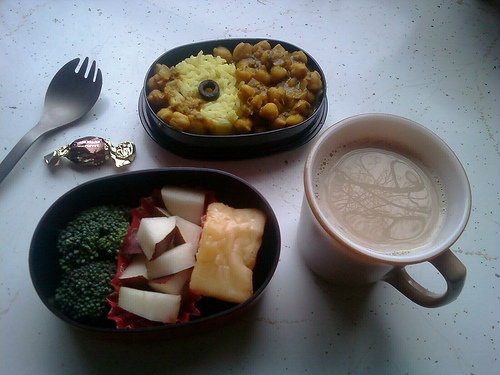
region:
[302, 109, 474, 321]
coffee in coffee mug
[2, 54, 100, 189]
plastic gray fork spoon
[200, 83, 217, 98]
lone black sliced olive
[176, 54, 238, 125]
yellow cooked rice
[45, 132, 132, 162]
candy with yellow and brown candy wrapper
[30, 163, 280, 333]
black plastic round dish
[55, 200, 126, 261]
green cooked broccolli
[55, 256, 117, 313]
green broccolli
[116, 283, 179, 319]
slice of potato with skin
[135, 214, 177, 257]
slice of potato with skin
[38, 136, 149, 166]
a wrapped sweet on the table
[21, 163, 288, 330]
a plate of food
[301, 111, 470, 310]
a white cup of coffee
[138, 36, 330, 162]
a plate of food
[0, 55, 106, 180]
a black fork on the table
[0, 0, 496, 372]
a set table for one person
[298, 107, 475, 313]
tea in a cup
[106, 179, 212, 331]
chopped mangoes in a plate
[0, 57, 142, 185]
a fork and a sweet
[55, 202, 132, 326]
green vegetables in a plate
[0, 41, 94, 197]
the spork is gray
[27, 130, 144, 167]
the candy has a brown and gold wrapper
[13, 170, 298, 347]
green broccoli in a bowl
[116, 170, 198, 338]
white apple in a bowl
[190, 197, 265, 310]
yellow cheese in a bowl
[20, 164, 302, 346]
the bowl is black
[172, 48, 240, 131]
white rice in a bowl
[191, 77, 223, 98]
black olive in the rice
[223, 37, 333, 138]
beans in the bowl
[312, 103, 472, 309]
coffee in the mug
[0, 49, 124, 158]
metal spork on table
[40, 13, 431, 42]
white table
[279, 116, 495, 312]
coffee in mug reflecting outdoors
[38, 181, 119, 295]
broccoli in black tin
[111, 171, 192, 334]
apple cut in red paper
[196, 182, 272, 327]
cheese in black tin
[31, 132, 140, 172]
candy on table by food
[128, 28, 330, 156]
black tin with hot food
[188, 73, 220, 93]
black olive on rice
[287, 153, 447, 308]
brown coffee mug on table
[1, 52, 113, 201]
a grey plastic spork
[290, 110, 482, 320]
a white mug with hot chocolate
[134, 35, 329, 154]
a oval shaped container containing food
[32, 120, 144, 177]
a piece of candy on the table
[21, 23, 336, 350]
two black dishes containing food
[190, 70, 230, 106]
one sliced piece of a black olive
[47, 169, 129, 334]
two pieces of broccoli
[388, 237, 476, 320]
a tan handle on a mug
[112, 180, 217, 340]
sliced fruit in a bowl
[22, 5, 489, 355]
black dots on the counter